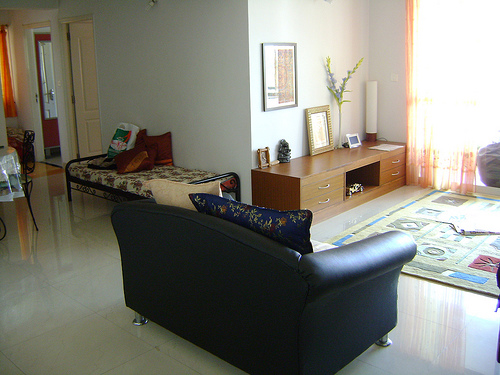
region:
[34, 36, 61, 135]
mirror hanging on red wall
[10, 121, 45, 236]
black wrought iron chair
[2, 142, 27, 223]
white tablecloth with border on table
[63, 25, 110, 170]
open white door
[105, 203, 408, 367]
back of black leather couch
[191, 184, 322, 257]
blue accent pillow with floral design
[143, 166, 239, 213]
square white accent pillow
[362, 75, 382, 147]
tall white candle in holder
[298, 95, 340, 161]
framed picture on wooden chest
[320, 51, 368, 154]
yellow flowers in a vase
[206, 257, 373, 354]
the couch is black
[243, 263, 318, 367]
the couch is black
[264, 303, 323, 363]
the couch is black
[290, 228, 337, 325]
the couch is black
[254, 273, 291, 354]
the couch is black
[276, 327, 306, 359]
the couch is black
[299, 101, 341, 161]
large gold frame leaning up against the wall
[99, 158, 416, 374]
small black leather couch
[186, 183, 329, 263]
dark blue throw pillow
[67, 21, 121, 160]
white door hanging open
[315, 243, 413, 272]
light shining on the leather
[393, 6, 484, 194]
sheer curtains pulled over the window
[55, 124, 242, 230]
bench with pillows on it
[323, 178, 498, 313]
area rug on the floor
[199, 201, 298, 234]
patterns on the pillow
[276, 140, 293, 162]
small figurine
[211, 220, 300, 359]
the couch is black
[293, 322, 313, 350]
the couch is black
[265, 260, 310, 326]
the couch is black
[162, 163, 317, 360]
the couch is black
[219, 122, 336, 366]
the couch is black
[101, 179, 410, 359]
blue leather sofa with pillow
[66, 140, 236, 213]
daybed against the wall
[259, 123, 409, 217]
short table against wall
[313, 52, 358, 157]
vase holding tall flower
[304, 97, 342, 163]
framed portrait on table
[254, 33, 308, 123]
framed picture on wall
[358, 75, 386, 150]
tall lamp in corner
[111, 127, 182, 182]
three pilllows on bed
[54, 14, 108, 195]
door to another room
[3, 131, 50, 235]
table and chair in room